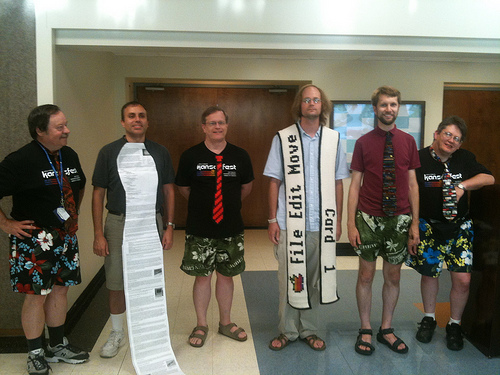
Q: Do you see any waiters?
A: No, there are no waiters.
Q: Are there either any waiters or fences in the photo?
A: No, there are no waiters or fences.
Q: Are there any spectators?
A: No, there are no spectators.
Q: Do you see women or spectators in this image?
A: No, there are no spectators or women.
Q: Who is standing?
A: The man is standing.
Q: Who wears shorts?
A: The man wears shorts.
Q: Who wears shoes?
A: The man wears shoes.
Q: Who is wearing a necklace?
A: The man is wearing a necklace.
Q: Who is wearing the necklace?
A: The man is wearing a necklace.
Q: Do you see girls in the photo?
A: No, there are no girls.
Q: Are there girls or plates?
A: No, there are no girls or plates.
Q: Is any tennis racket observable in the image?
A: No, there are no rackets.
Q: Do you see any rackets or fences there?
A: No, there are no rackets or fences.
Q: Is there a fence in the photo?
A: No, there are no fences.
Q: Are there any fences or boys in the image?
A: No, there are no fences or boys.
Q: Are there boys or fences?
A: No, there are no boys or fences.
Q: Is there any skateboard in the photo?
A: No, there are no skateboards.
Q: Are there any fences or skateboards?
A: No, there are no skateboards or fences.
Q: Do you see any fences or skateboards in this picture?
A: No, there are no skateboards or fences.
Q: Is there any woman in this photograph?
A: No, there are no women.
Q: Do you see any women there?
A: No, there are no women.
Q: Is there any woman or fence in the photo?
A: No, there are no women or fences.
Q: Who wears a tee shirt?
A: The man wears a tee shirt.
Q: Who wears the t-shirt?
A: The man wears a tee shirt.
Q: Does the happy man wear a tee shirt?
A: Yes, the man wears a tee shirt.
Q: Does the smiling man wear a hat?
A: No, the man wears a tee shirt.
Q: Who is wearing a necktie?
A: The man is wearing a necktie.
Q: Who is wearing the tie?
A: The man is wearing a necktie.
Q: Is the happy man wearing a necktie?
A: Yes, the man is wearing a necktie.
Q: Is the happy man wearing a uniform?
A: No, the man is wearing a necktie.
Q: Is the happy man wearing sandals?
A: Yes, the man is wearing sandals.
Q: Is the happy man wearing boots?
A: No, the man is wearing sandals.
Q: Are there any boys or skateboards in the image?
A: No, there are no boys or skateboards.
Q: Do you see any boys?
A: No, there are no boys.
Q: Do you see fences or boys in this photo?
A: No, there are no boys or fences.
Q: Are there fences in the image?
A: No, there are no fences.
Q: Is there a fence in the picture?
A: No, there are no fences.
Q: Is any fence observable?
A: No, there are no fences.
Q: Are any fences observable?
A: No, there are no fences.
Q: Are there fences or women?
A: No, there are no fences or women.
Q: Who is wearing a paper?
A: The man is wearing a paper.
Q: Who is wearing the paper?
A: The man is wearing a paper.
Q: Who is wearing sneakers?
A: The man is wearing sneakers.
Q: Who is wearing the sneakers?
A: The man is wearing sneakers.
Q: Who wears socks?
A: The man wears socks.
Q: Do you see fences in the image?
A: No, there are no fences.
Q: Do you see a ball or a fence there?
A: No, there are no fences or balls.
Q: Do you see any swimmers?
A: No, there are no swimmers.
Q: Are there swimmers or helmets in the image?
A: No, there are no swimmers or helmets.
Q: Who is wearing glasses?
A: The man is wearing glasses.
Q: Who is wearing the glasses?
A: The man is wearing glasses.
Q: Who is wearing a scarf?
A: The man is wearing a scarf.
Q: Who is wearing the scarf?
A: The man is wearing a scarf.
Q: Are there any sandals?
A: Yes, there are sandals.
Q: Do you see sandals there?
A: Yes, there are sandals.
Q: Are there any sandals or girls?
A: Yes, there are sandals.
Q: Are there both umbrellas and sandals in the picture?
A: No, there are sandals but no umbrellas.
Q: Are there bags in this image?
A: No, there are no bags.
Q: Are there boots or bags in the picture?
A: No, there are no bags or boots.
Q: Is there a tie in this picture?
A: Yes, there is a tie.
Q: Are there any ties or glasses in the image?
A: Yes, there is a tie.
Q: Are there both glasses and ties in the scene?
A: Yes, there are both a tie and glasses.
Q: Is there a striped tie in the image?
A: Yes, there is a striped tie.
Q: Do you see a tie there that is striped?
A: Yes, there is a tie that is striped.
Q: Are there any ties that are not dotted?
A: Yes, there is a striped tie.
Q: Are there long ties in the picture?
A: Yes, there is a long tie.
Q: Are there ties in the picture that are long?
A: Yes, there is a tie that is long.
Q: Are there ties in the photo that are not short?
A: Yes, there is a long tie.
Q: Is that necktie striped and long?
A: Yes, the necktie is striped and long.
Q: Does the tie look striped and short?
A: No, the tie is striped but long.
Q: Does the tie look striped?
A: Yes, the tie is striped.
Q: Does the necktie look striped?
A: Yes, the necktie is striped.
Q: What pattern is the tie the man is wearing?
A: The necktie is striped.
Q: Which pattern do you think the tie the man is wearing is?
A: The necktie is striped.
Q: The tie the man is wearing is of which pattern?
A: The necktie is striped.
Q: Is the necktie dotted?
A: No, the necktie is striped.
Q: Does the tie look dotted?
A: No, the tie is striped.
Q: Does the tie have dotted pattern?
A: No, the tie is striped.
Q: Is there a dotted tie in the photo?
A: No, there is a tie but it is striped.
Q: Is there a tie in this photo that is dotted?
A: No, there is a tie but it is striped.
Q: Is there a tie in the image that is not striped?
A: No, there is a tie but it is striped.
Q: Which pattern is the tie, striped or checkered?
A: The tie is striped.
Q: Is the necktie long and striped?
A: Yes, the necktie is long and striped.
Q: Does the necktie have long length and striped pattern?
A: Yes, the necktie is long and striped.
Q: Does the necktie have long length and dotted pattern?
A: No, the necktie is long but striped.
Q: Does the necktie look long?
A: Yes, the necktie is long.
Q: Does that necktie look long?
A: Yes, the necktie is long.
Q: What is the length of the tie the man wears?
A: The necktie is long.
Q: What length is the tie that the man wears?
A: The necktie is long.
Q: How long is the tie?
A: The tie is long.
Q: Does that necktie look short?
A: No, the necktie is long.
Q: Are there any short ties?
A: No, there is a tie but it is long.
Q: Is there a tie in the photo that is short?
A: No, there is a tie but it is long.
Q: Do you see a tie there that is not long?
A: No, there is a tie but it is long.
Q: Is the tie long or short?
A: The tie is long.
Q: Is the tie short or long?
A: The tie is long.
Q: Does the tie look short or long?
A: The tie is long.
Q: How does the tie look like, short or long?
A: The tie is long.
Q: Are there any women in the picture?
A: No, there are no women.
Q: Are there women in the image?
A: No, there are no women.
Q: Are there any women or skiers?
A: No, there are no women or skiers.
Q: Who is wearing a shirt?
A: The man is wearing a shirt.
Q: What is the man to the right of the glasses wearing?
A: The man is wearing a shirt.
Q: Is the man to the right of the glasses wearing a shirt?
A: Yes, the man is wearing a shirt.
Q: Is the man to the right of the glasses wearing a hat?
A: No, the man is wearing a shirt.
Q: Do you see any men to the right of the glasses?
A: Yes, there is a man to the right of the glasses.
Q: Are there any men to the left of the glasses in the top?
A: No, the man is to the right of the glasses.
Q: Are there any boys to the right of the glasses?
A: No, there is a man to the right of the glasses.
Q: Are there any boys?
A: No, there are no boys.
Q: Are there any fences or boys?
A: No, there are no boys or fences.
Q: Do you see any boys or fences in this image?
A: No, there are no boys or fences.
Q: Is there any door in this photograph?
A: Yes, there is a door.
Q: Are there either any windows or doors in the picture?
A: Yes, there is a door.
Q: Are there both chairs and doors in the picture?
A: No, there is a door but no chairs.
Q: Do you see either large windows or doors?
A: Yes, there is a large door.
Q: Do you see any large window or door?
A: Yes, there is a large door.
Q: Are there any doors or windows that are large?
A: Yes, the door is large.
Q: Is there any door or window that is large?
A: Yes, the door is large.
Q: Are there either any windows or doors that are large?
A: Yes, the door is large.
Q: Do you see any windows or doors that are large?
A: Yes, the door is large.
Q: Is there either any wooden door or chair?
A: Yes, there is a wood door.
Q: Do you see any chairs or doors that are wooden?
A: Yes, the door is wooden.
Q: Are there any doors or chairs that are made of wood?
A: Yes, the door is made of wood.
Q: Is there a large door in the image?
A: Yes, there is a large door.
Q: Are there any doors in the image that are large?
A: Yes, there is a door that is large.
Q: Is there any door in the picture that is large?
A: Yes, there is a door that is large.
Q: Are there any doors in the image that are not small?
A: Yes, there is a large door.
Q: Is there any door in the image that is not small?
A: Yes, there is a large door.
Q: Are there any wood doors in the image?
A: Yes, there is a wood door.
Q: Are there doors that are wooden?
A: Yes, there is a door that is wooden.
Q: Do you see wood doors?
A: Yes, there is a door that is made of wood.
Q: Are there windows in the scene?
A: No, there are no windows.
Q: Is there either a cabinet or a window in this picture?
A: No, there are no windows or cabinets.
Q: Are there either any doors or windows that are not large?
A: No, there is a door but it is large.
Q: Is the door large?
A: Yes, the door is large.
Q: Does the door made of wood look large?
A: Yes, the door is large.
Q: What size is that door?
A: The door is large.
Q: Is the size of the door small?
A: No, the door is large.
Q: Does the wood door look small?
A: No, the door is large.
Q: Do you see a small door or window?
A: No, there is a door but it is large.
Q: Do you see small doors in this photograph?
A: No, there is a door but it is large.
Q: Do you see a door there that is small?
A: No, there is a door but it is large.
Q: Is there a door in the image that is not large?
A: No, there is a door but it is large.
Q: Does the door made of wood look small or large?
A: The door is large.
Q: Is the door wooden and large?
A: Yes, the door is wooden and large.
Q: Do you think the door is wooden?
A: Yes, the door is wooden.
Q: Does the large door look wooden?
A: Yes, the door is wooden.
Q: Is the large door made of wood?
A: Yes, the door is made of wood.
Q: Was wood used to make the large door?
A: Yes, the door is made of wood.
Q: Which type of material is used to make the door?
A: The door is made of wood.